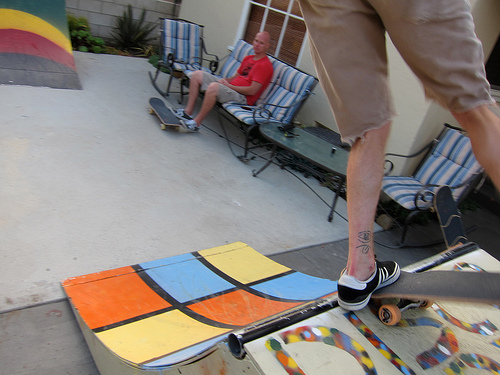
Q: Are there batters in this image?
A: No, there are no batters.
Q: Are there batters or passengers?
A: No, there are no batters or passengers.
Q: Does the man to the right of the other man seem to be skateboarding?
A: Yes, the man is skateboarding.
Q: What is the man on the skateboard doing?
A: The man is skateboarding.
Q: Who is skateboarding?
A: The man is skateboarding.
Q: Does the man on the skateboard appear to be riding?
A: No, the man is skateboarding.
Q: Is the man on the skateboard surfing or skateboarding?
A: The man is skateboarding.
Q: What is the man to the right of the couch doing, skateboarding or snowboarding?
A: The man is skateboarding.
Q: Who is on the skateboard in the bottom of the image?
A: The man is on the skateboard.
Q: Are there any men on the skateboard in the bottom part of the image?
A: Yes, there is a man on the skateboard.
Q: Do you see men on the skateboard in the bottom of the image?
A: Yes, there is a man on the skateboard.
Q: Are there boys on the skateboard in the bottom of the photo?
A: No, there is a man on the skateboard.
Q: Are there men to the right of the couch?
A: Yes, there is a man to the right of the couch.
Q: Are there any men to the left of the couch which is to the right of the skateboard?
A: No, the man is to the right of the couch.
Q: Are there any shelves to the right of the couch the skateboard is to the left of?
A: No, there is a man to the right of the couch.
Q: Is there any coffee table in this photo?
A: Yes, there is a coffee table.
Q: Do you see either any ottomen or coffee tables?
A: Yes, there is a coffee table.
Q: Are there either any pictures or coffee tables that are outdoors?
A: Yes, the coffee table is outdoors.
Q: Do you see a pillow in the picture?
A: No, there are no pillows.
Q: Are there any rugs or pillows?
A: No, there are no pillows or rugs.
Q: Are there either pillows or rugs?
A: No, there are no pillows or rugs.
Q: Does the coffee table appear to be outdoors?
A: Yes, the coffee table is outdoors.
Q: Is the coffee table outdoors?
A: Yes, the coffee table is outdoors.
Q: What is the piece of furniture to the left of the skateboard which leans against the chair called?
A: The piece of furniture is a coffee table.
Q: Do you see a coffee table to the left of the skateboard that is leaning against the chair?
A: Yes, there is a coffee table to the left of the skateboard.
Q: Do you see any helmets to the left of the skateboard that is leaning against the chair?
A: No, there is a coffee table to the left of the skateboard.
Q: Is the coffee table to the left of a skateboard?
A: Yes, the coffee table is to the left of a skateboard.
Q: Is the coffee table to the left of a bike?
A: No, the coffee table is to the left of a skateboard.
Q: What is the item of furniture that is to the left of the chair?
A: The piece of furniture is a coffee table.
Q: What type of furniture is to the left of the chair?
A: The piece of furniture is a coffee table.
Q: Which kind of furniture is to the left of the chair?
A: The piece of furniture is a coffee table.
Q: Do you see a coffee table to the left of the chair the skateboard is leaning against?
A: Yes, there is a coffee table to the left of the chair.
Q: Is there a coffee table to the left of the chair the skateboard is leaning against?
A: Yes, there is a coffee table to the left of the chair.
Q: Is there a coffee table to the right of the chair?
A: No, the coffee table is to the left of the chair.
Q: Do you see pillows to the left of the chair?
A: No, there is a coffee table to the left of the chair.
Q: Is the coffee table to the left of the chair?
A: Yes, the coffee table is to the left of the chair.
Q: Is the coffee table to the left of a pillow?
A: No, the coffee table is to the left of the chair.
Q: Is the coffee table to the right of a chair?
A: No, the coffee table is to the left of a chair.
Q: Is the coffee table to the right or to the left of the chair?
A: The coffee table is to the left of the chair.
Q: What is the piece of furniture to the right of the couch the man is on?
A: The piece of furniture is a coffee table.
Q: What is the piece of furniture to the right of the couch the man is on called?
A: The piece of furniture is a coffee table.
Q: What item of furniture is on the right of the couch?
A: The piece of furniture is a coffee table.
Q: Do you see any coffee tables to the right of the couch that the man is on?
A: Yes, there is a coffee table to the right of the couch.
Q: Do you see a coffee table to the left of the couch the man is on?
A: No, the coffee table is to the right of the couch.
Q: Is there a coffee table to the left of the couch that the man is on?
A: No, the coffee table is to the right of the couch.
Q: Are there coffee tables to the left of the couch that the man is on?
A: No, the coffee table is to the right of the couch.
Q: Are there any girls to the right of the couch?
A: No, there is a coffee table to the right of the couch.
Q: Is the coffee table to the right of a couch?
A: Yes, the coffee table is to the right of a couch.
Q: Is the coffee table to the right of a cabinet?
A: No, the coffee table is to the right of a couch.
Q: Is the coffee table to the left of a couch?
A: No, the coffee table is to the right of a couch.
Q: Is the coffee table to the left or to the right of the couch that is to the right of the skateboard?
A: The coffee table is to the right of the couch.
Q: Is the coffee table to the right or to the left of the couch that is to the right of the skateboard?
A: The coffee table is to the right of the couch.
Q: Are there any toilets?
A: No, there are no toilets.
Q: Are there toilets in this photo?
A: No, there are no toilets.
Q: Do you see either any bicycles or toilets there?
A: No, there are no toilets or bicycles.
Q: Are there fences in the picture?
A: No, there are no fences.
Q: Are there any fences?
A: No, there are no fences.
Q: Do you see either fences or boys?
A: No, there are no fences or boys.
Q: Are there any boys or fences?
A: No, there are no fences or boys.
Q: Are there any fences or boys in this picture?
A: No, there are no fences or boys.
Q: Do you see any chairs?
A: Yes, there is a chair.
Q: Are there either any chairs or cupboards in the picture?
A: Yes, there is a chair.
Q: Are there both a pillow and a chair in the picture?
A: No, there is a chair but no pillows.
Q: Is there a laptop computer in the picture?
A: No, there are no laptops.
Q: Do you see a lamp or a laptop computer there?
A: No, there are no laptops or lamps.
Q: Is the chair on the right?
A: Yes, the chair is on the right of the image.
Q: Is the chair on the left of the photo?
A: No, the chair is on the right of the image.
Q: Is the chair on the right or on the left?
A: The chair is on the right of the image.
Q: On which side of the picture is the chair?
A: The chair is on the right of the image.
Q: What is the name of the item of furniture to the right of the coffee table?
A: The piece of furniture is a chair.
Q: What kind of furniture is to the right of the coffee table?
A: The piece of furniture is a chair.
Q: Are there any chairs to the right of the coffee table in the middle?
A: Yes, there is a chair to the right of the coffee table.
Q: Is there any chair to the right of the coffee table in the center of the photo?
A: Yes, there is a chair to the right of the coffee table.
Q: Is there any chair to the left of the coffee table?
A: No, the chair is to the right of the coffee table.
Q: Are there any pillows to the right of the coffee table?
A: No, there is a chair to the right of the coffee table.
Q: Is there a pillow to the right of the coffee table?
A: No, there is a chair to the right of the coffee table.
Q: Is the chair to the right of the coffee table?
A: Yes, the chair is to the right of the coffee table.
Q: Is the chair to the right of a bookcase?
A: No, the chair is to the right of the coffee table.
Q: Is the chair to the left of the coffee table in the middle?
A: No, the chair is to the right of the coffee table.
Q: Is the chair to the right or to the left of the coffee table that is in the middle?
A: The chair is to the right of the coffee table.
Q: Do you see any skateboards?
A: Yes, there is a skateboard.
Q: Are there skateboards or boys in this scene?
A: Yes, there is a skateboard.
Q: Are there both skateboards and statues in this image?
A: No, there is a skateboard but no statues.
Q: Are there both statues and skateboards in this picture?
A: No, there is a skateboard but no statues.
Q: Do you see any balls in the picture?
A: No, there are no balls.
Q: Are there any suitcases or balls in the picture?
A: No, there are no balls or suitcases.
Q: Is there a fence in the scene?
A: No, there are no fences.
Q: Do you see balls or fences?
A: No, there are no fences or balls.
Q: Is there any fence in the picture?
A: No, there are no fences.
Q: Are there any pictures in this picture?
A: No, there are no pictures.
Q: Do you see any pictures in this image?
A: No, there are no pictures.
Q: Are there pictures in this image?
A: No, there are no pictures.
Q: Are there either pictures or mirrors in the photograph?
A: No, there are no pictures or mirrors.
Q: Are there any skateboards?
A: Yes, there is a skateboard.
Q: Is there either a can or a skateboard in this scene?
A: Yes, there is a skateboard.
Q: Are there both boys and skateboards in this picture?
A: No, there is a skateboard but no boys.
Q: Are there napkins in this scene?
A: No, there are no napkins.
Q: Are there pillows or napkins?
A: No, there are no napkins or pillows.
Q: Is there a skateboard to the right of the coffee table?
A: Yes, there is a skateboard to the right of the coffee table.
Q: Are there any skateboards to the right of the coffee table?
A: Yes, there is a skateboard to the right of the coffee table.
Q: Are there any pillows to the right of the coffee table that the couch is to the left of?
A: No, there is a skateboard to the right of the coffee table.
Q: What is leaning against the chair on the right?
A: The skateboard is leaning against the chair.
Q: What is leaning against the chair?
A: The skateboard is leaning against the chair.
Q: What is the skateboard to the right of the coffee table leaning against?
A: The skateboard is leaning against the chair.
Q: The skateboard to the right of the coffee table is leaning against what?
A: The skateboard is leaning against the chair.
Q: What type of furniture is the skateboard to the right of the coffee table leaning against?
A: The skateboard is leaning against the chair.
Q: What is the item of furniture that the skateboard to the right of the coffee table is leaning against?
A: The piece of furniture is a chair.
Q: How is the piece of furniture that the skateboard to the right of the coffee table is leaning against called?
A: The piece of furniture is a chair.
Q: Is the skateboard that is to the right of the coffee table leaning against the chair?
A: Yes, the skateboard is leaning against the chair.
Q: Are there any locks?
A: No, there are no locks.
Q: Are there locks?
A: No, there are no locks.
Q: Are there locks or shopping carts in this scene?
A: No, there are no locks or shopping carts.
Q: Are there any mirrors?
A: No, there are no mirrors.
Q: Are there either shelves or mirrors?
A: No, there are no mirrors or shelves.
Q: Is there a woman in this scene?
A: No, there are no women.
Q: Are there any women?
A: No, there are no women.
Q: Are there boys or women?
A: No, there are no women or boys.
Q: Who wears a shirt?
A: The man wears a shirt.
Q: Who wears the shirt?
A: The man wears a shirt.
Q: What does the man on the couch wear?
A: The man wears a shirt.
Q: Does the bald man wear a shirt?
A: Yes, the man wears a shirt.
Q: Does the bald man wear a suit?
A: No, the man wears a shirt.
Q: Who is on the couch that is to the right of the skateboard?
A: The man is on the couch.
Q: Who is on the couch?
A: The man is on the couch.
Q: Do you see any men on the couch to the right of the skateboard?
A: Yes, there is a man on the couch.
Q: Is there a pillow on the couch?
A: No, there is a man on the couch.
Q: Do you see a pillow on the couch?
A: No, there is a man on the couch.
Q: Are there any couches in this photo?
A: Yes, there is a couch.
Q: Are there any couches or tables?
A: Yes, there is a couch.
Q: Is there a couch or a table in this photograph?
A: Yes, there is a couch.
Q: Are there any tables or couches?
A: Yes, there is a couch.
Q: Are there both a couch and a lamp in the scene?
A: No, there is a couch but no lamps.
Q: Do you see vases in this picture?
A: No, there are no vases.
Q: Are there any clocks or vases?
A: No, there are no vases or clocks.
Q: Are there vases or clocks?
A: No, there are no vases or clocks.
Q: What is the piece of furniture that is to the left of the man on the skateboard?
A: The piece of furniture is a couch.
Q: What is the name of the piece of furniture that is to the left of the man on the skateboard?
A: The piece of furniture is a couch.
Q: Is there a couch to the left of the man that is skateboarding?
A: Yes, there is a couch to the left of the man.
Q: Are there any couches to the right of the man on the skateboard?
A: No, the couch is to the left of the man.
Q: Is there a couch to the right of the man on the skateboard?
A: No, the couch is to the left of the man.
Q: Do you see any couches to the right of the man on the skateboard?
A: No, the couch is to the left of the man.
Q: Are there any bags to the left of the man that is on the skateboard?
A: No, there is a couch to the left of the man.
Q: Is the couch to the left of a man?
A: Yes, the couch is to the left of a man.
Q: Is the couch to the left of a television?
A: No, the couch is to the left of a man.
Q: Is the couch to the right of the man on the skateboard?
A: No, the couch is to the left of the man.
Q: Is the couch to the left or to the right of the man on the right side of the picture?
A: The couch is to the left of the man.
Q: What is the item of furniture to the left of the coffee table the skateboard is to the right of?
A: The piece of furniture is a couch.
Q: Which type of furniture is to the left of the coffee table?
A: The piece of furniture is a couch.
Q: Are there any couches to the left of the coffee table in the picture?
A: Yes, there is a couch to the left of the coffee table.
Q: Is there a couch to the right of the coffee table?
A: No, the couch is to the left of the coffee table.